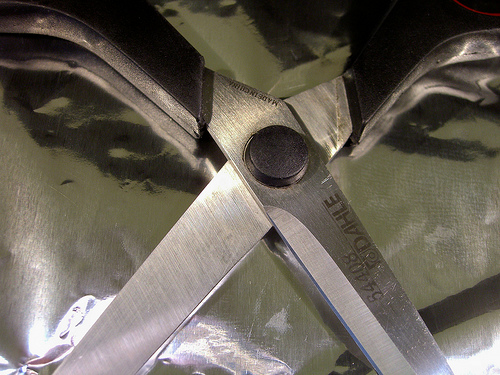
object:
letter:
[335, 211, 356, 229]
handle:
[2, 2, 213, 128]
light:
[459, 353, 498, 372]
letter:
[332, 202, 347, 217]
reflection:
[379, 92, 500, 163]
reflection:
[11, 96, 207, 199]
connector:
[245, 123, 310, 189]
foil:
[0, 280, 36, 341]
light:
[22, 316, 49, 353]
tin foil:
[441, 184, 490, 270]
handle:
[340, 5, 496, 159]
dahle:
[322, 191, 372, 252]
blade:
[57, 59, 363, 373]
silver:
[171, 197, 239, 279]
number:
[367, 291, 384, 302]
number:
[360, 281, 376, 291]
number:
[354, 271, 370, 281]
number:
[348, 263, 364, 273]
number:
[342, 253, 358, 264]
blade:
[199, 64, 453, 373]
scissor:
[1, 3, 498, 373]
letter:
[322, 193, 341, 208]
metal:
[68, 339, 117, 370]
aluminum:
[23, 228, 46, 263]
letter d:
[352, 235, 371, 253]